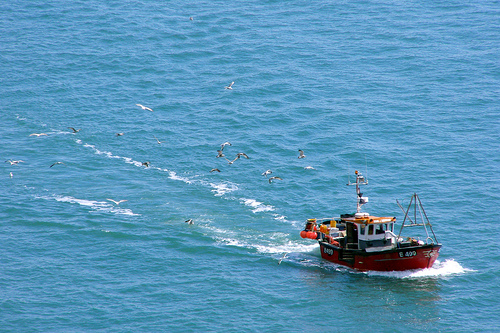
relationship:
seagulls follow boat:
[6, 74, 391, 239] [292, 176, 479, 286]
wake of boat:
[50, 127, 301, 269] [298, 167, 445, 278]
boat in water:
[299, 169, 440, 274] [2, 3, 494, 330]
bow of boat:
[409, 239, 447, 271] [303, 167, 441, 272]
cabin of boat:
[340, 210, 398, 250] [318, 166, 441, 271]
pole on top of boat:
[340, 166, 369, 222] [320, 132, 413, 331]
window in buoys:
[340, 228, 360, 249] [182, 137, 354, 215]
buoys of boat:
[182, 137, 354, 215] [296, 179, 445, 273]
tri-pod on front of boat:
[393, 192, 441, 246] [303, 167, 441, 272]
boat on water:
[299, 169, 440, 274] [270, 39, 482, 141]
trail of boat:
[63, 133, 305, 245] [318, 166, 441, 271]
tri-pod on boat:
[391, 188, 441, 249] [298, 167, 445, 278]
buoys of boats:
[182, 137, 354, 215] [295, 169, 446, 287]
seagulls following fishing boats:
[142, 115, 296, 204] [302, 170, 440, 273]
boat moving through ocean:
[306, 173, 445, 268] [2, 0, 499, 332]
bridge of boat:
[343, 209, 395, 248] [303, 167, 441, 272]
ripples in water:
[83, 139, 311, 238] [1, 3, 308, 328]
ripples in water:
[45, 184, 295, 280] [1, 3, 308, 328]